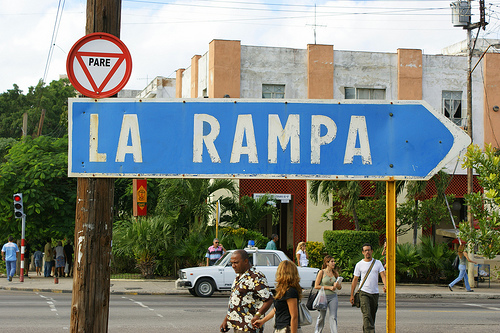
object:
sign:
[65, 96, 472, 182]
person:
[348, 243, 390, 331]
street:
[2, 271, 499, 330]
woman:
[447, 239, 477, 298]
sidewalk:
[0, 267, 498, 296]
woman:
[249, 257, 304, 330]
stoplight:
[12, 189, 28, 226]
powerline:
[121, 0, 495, 17]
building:
[133, 41, 500, 279]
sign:
[64, 30, 134, 99]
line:
[36, 287, 69, 328]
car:
[167, 244, 330, 298]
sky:
[4, 1, 499, 87]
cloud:
[10, 4, 493, 89]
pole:
[67, 1, 122, 331]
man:
[216, 247, 272, 330]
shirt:
[227, 271, 271, 330]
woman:
[300, 252, 356, 331]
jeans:
[313, 293, 341, 331]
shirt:
[353, 256, 385, 293]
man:
[2, 236, 22, 286]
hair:
[274, 259, 300, 301]